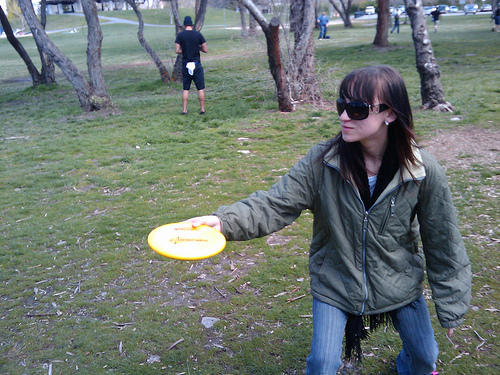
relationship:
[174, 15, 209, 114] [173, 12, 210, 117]
he has backside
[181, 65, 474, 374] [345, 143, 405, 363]
people wearing scarf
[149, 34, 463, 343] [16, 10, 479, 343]
people in park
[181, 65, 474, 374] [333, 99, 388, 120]
people in sunglasses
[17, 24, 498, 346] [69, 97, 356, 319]
ground with grass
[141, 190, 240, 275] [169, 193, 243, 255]
frisbee in hand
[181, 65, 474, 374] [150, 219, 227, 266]
people holding frisbee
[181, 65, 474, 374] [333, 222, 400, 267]
people wearing a green jacket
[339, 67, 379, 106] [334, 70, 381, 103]
bangs are her bangs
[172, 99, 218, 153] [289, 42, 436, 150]
he has a black beanie on h head